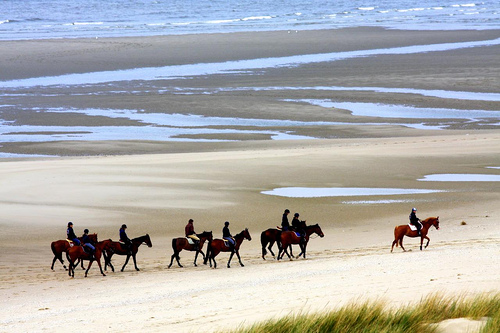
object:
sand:
[0, 25, 500, 331]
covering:
[405, 220, 425, 235]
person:
[65, 222, 80, 244]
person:
[118, 222, 134, 254]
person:
[292, 211, 306, 240]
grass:
[233, 301, 432, 331]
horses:
[386, 216, 440, 253]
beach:
[0, 25, 500, 332]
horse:
[202, 226, 254, 269]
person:
[220, 218, 239, 251]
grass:
[230, 289, 500, 332]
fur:
[75, 247, 82, 257]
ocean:
[0, 0, 500, 41]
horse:
[273, 223, 327, 261]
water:
[260, 184, 445, 197]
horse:
[98, 233, 153, 271]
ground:
[0, 26, 499, 331]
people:
[407, 206, 422, 235]